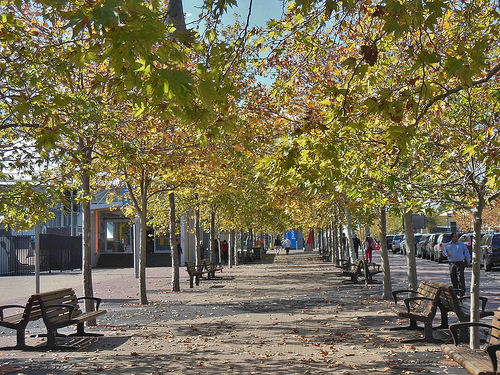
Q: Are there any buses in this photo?
A: No, there are no buses.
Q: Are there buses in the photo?
A: No, there are no buses.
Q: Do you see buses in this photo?
A: No, there are no buses.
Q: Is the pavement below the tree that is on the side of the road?
A: Yes, the pavement is below the tree.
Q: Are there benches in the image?
A: Yes, there is a bench.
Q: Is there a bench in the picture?
A: Yes, there is a bench.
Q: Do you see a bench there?
A: Yes, there is a bench.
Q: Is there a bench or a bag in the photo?
A: Yes, there is a bench.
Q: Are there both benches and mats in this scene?
A: No, there is a bench but no mats.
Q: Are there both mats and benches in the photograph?
A: No, there is a bench but no mats.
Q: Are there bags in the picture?
A: No, there are no bags.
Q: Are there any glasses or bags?
A: No, there are no bags or glasses.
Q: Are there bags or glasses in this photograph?
A: No, there are no bags or glasses.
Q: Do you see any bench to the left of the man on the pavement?
A: Yes, there is a bench to the left of the man.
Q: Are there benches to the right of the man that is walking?
A: No, the bench is to the left of the man.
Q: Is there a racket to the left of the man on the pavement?
A: No, there is a bench to the left of the man.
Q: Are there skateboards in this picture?
A: No, there are no skateboards.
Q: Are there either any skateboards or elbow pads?
A: No, there are no skateboards or elbow pads.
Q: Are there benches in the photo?
A: Yes, there is a bench.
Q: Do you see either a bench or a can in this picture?
A: Yes, there is a bench.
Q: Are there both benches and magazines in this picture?
A: No, there is a bench but no magazines.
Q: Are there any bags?
A: No, there are no bags.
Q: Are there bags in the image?
A: No, there are no bags.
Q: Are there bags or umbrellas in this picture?
A: No, there are no bags or umbrellas.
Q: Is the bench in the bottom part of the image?
A: Yes, the bench is in the bottom of the image.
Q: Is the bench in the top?
A: No, the bench is in the bottom of the image.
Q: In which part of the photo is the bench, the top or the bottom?
A: The bench is in the bottom of the image.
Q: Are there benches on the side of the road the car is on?
A: Yes, there is a bench on the side of the road.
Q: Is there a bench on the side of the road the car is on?
A: Yes, there is a bench on the side of the road.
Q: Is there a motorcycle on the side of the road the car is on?
A: No, there is a bench on the side of the road.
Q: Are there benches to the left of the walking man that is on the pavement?
A: Yes, there is a bench to the left of the man.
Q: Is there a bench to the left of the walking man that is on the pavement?
A: Yes, there is a bench to the left of the man.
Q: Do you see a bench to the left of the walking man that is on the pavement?
A: Yes, there is a bench to the left of the man.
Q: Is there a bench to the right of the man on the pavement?
A: No, the bench is to the left of the man.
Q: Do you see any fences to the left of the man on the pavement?
A: No, there is a bench to the left of the man.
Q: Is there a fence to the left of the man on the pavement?
A: No, there is a bench to the left of the man.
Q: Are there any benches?
A: Yes, there is a bench.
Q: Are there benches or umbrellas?
A: Yes, there is a bench.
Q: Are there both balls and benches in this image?
A: No, there is a bench but no balls.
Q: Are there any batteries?
A: No, there are no batteries.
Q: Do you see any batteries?
A: No, there are no batteries.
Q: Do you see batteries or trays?
A: No, there are no batteries or trays.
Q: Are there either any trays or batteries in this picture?
A: No, there are no batteries or trays.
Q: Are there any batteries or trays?
A: No, there are no batteries or trays.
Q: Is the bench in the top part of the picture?
A: No, the bench is in the bottom of the image.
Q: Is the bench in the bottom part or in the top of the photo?
A: The bench is in the bottom of the image.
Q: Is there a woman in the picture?
A: Yes, there is a woman.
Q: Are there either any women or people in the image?
A: Yes, there is a woman.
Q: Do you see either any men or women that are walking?
A: Yes, the woman is walking.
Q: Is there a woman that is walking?
A: Yes, there is a woman that is walking.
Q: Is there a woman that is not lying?
A: Yes, there is a woman that is walking.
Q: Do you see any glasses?
A: No, there are no glasses.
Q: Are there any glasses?
A: No, there are no glasses.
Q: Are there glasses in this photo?
A: No, there are no glasses.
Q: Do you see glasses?
A: No, there are no glasses.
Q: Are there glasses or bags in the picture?
A: No, there are no glasses or bags.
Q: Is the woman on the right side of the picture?
A: Yes, the woman is on the right of the image.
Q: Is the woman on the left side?
A: No, the woman is on the right of the image.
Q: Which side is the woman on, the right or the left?
A: The woman is on the right of the image.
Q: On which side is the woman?
A: The woman is on the right of the image.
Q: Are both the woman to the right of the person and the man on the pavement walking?
A: Yes, both the woman and the man are walking.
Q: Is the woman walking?
A: Yes, the woman is walking.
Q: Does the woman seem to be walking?
A: Yes, the woman is walking.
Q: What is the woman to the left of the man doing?
A: The woman is walking.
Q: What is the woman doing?
A: The woman is walking.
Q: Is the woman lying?
A: No, the woman is walking.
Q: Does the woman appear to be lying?
A: No, the woman is walking.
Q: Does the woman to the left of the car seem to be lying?
A: No, the woman is walking.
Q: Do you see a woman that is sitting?
A: No, there is a woman but she is walking.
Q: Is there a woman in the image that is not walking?
A: No, there is a woman but she is walking.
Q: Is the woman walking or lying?
A: The woman is walking.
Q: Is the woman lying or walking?
A: The woman is walking.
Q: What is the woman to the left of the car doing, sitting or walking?
A: The woman is walking.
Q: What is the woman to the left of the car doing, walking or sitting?
A: The woman is walking.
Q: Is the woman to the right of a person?
A: Yes, the woman is to the right of a person.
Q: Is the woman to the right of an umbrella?
A: No, the woman is to the right of a person.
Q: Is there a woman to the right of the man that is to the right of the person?
A: Yes, there is a woman to the right of the man.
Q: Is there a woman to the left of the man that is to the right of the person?
A: No, the woman is to the right of the man.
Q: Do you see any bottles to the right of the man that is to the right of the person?
A: No, there is a woman to the right of the man.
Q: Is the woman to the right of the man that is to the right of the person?
A: Yes, the woman is to the right of the man.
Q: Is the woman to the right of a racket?
A: No, the woman is to the right of the man.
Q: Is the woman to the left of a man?
A: No, the woman is to the right of a man.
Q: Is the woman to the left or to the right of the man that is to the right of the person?
A: The woman is to the right of the man.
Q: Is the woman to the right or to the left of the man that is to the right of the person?
A: The woman is to the right of the man.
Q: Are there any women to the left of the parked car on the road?
A: Yes, there is a woman to the left of the car.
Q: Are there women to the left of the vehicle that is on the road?
A: Yes, there is a woman to the left of the car.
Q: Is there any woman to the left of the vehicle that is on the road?
A: Yes, there is a woman to the left of the car.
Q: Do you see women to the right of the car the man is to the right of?
A: No, the woman is to the left of the car.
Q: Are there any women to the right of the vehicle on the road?
A: No, the woman is to the left of the car.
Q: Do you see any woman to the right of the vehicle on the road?
A: No, the woman is to the left of the car.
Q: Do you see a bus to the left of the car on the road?
A: No, there is a woman to the left of the car.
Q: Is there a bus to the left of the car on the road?
A: No, there is a woman to the left of the car.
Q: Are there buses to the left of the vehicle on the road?
A: No, there is a woman to the left of the car.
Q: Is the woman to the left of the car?
A: Yes, the woman is to the left of the car.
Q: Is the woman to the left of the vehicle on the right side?
A: Yes, the woman is to the left of the car.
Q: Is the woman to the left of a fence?
A: No, the woman is to the left of the car.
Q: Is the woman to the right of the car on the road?
A: No, the woman is to the left of the car.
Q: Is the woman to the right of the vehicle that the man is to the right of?
A: No, the woman is to the left of the car.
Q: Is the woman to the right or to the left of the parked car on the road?
A: The woman is to the left of the car.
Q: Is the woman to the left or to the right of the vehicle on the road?
A: The woman is to the left of the car.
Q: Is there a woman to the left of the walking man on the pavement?
A: Yes, there is a woman to the left of the man.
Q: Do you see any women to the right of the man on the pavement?
A: No, the woman is to the left of the man.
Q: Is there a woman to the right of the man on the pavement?
A: No, the woman is to the left of the man.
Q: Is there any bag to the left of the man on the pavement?
A: No, there is a woman to the left of the man.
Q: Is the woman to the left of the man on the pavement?
A: Yes, the woman is to the left of the man.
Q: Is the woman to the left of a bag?
A: No, the woman is to the left of the man.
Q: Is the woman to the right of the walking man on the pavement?
A: No, the woman is to the left of the man.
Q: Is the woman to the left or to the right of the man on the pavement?
A: The woman is to the left of the man.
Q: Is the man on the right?
A: Yes, the man is on the right of the image.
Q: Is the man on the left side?
A: No, the man is on the right of the image.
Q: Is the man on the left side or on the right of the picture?
A: The man is on the right of the image.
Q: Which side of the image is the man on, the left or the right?
A: The man is on the right of the image.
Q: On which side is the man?
A: The man is on the right of the image.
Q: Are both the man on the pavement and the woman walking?
A: Yes, both the man and the woman are walking.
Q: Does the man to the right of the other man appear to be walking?
A: Yes, the man is walking.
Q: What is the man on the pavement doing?
A: The man is walking.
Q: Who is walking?
A: The man is walking.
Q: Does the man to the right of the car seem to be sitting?
A: No, the man is walking.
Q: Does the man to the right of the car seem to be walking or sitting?
A: The man is walking.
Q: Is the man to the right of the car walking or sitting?
A: The man is walking.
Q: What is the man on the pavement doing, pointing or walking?
A: The man is walking.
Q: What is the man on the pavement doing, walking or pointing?
A: The man is walking.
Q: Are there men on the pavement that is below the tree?
A: Yes, there is a man on the pavement.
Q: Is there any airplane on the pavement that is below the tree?
A: No, there is a man on the pavement.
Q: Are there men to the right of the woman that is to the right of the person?
A: Yes, there is a man to the right of the woman.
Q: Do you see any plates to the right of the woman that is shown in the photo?
A: No, there is a man to the right of the woman.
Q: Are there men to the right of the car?
A: Yes, there is a man to the right of the car.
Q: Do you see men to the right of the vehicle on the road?
A: Yes, there is a man to the right of the car.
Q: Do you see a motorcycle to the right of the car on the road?
A: No, there is a man to the right of the car.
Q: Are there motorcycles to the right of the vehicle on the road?
A: No, there is a man to the right of the car.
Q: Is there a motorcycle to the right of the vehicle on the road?
A: No, there is a man to the right of the car.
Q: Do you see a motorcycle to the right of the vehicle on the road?
A: No, there is a man to the right of the car.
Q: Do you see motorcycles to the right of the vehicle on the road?
A: No, there is a man to the right of the car.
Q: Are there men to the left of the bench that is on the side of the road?
A: No, the man is to the right of the bench.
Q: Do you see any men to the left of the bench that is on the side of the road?
A: No, the man is to the right of the bench.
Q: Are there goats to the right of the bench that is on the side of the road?
A: No, there is a man to the right of the bench.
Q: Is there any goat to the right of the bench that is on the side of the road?
A: No, there is a man to the right of the bench.